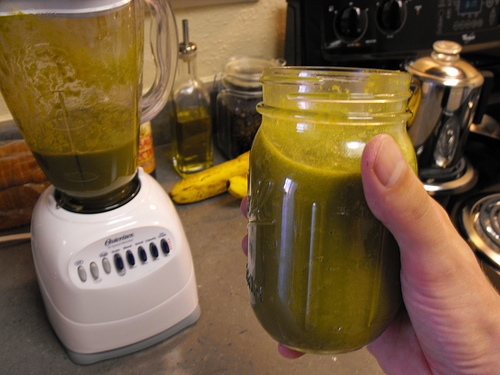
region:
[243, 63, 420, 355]
green salsa in a glass jar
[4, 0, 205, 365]
white blender on the counter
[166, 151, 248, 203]
ripe bananas on the counter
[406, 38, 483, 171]
silver tea kettle on the stove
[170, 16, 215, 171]
bottle of olive oil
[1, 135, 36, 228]
loaf of sliced bread in a bag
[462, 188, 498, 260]
electric burner on stove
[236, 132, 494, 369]
hand holding up a jar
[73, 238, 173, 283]
several buttons on the blender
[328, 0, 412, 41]
knobs on the back of the stove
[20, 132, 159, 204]
green liquid in blender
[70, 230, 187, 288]
speed control buttons on blender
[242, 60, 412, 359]
jar of green liquid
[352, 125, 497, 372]
right thumb of person holding green liquid jar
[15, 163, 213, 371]
white base of blender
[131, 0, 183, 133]
glass handle of blender jar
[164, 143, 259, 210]
brown and yellow ripe bananas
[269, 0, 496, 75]
stove and oven temperature controls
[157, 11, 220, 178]
jar of green clear oil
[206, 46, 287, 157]
container with dark contents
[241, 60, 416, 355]
Jar of green liquid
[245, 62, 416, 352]
Jar filled with a green liquid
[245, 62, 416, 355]
Green liquid inside a jar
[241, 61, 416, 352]
Green liquid contained in a jar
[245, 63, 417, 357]
Jar containing a green liquid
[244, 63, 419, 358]
Jar containing a green smoothie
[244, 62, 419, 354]
Jar filled with a green smoothie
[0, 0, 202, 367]
Blender with a green smoothie inside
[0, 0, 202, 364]
Blender used to make a green smoothie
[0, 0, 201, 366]
Blender with a white base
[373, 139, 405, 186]
thumbnail of persons thumb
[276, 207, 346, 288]
green shake in jar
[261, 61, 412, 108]
top of uncovered jar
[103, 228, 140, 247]
black lettering on mixer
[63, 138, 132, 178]
green shake in mixer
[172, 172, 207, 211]
bottom of yellow banana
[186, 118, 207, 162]
olive oil in bottle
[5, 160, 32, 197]
loaf of bread by mixer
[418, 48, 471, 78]
top of closed silver tin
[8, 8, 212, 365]
This is a blender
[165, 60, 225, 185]
a jug of juice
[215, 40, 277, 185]
a jug of juice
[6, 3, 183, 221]
a jug of juice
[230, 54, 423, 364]
a jug of juice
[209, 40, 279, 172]
a jug of juice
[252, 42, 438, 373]
a jug of juice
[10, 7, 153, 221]
a jug of juice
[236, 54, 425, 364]
person holding a jar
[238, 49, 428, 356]
jar in hand is small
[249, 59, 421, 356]
jar in hand is full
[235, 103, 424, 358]
liquid in small jar is green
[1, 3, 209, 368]
blender on counter top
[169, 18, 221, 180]
bottle of oil on counter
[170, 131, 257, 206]
banana lying on counter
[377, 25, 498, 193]
coffee percolator on stove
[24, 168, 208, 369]
base of blender is white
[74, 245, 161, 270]
buttons on the blender